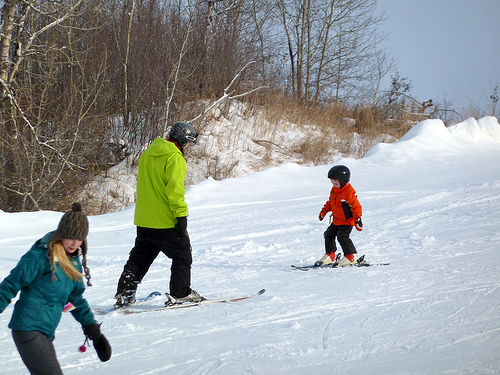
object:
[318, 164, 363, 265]
boy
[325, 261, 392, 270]
skis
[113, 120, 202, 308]
man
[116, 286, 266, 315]
skis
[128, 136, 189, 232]
jacket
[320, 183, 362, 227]
coat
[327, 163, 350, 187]
helmet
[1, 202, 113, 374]
woman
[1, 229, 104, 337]
coat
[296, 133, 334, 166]
grass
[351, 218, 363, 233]
mitts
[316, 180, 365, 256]
ski outfit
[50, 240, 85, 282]
hair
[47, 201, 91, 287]
hat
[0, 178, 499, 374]
ski tracks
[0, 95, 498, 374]
snow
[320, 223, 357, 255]
snow pants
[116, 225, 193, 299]
snow pants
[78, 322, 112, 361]
glove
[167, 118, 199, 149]
helmet